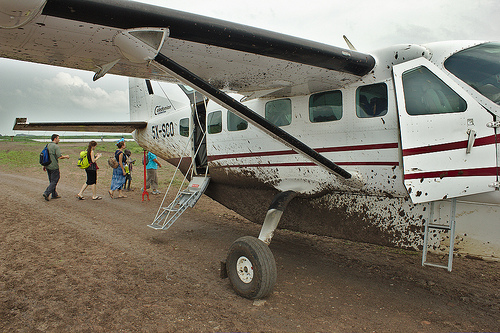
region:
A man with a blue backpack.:
[33, 120, 67, 208]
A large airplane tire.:
[216, 235, 283, 308]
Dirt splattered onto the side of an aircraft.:
[203, 164, 273, 213]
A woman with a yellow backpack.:
[75, 134, 104, 204]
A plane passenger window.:
[354, 80, 393, 121]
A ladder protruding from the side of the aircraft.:
[143, 172, 214, 238]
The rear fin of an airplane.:
[12, 114, 145, 135]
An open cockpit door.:
[386, 55, 496, 222]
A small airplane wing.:
[1, 0, 367, 102]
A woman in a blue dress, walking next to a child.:
[106, 135, 134, 203]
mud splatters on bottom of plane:
[217, 178, 344, 238]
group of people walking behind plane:
[39, 133, 158, 201]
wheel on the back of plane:
[217, 234, 281, 301]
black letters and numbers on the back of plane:
[149, 120, 176, 140]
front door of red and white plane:
[391, 54, 498, 199]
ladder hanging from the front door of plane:
[421, 201, 456, 278]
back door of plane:
[186, 102, 208, 177]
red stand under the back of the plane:
[137, 148, 151, 205]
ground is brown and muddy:
[310, 252, 380, 302]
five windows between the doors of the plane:
[207, 89, 391, 132]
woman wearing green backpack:
[65, 134, 100, 174]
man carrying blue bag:
[25, 129, 62, 176]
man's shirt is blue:
[135, 147, 166, 179]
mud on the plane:
[121, 98, 423, 286]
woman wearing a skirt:
[77, 161, 104, 184]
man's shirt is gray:
[41, 133, 62, 174]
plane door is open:
[366, 55, 496, 198]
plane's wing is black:
[52, 0, 394, 91]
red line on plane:
[195, 129, 494, 205]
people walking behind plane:
[29, 122, 195, 217]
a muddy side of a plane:
[168, 154, 440, 287]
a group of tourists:
[26, 133, 186, 217]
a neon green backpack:
[71, 148, 93, 174]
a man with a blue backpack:
[37, 129, 75, 208]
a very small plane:
[3, 3, 498, 298]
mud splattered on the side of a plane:
[154, 140, 487, 289]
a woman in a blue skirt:
[112, 135, 147, 204]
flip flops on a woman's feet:
[71, 192, 113, 206]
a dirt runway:
[12, 179, 248, 327]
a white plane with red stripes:
[83, 46, 496, 331]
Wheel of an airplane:
[218, 235, 277, 302]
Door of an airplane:
[392, 52, 499, 202]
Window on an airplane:
[307, 85, 344, 124]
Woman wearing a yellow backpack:
[76, 138, 104, 200]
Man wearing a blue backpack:
[37, 130, 64, 201]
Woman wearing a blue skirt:
[110, 140, 129, 202]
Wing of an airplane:
[6, 1, 376, 90]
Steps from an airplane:
[143, 155, 212, 233]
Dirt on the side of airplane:
[172, 156, 433, 249]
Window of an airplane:
[175, 115, 191, 138]